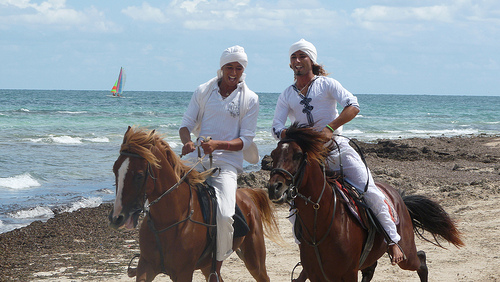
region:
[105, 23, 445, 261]
two riders talking to each other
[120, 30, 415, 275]
two people in white outfits and turbans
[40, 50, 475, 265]
brown horses running along beach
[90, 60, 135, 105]
colorful sailboat on the ocean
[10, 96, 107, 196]
small waves with white caps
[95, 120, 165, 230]
white stripe down the front of horse's head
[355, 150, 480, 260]
tail flying to one side of moving horse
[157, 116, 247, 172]
both hands holding the reins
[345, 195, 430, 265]
bare foot in a stirrup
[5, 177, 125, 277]
seaweed along the edge of the shore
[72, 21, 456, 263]
two men riding horses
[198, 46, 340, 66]
the turbans on the men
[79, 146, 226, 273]
the face of the white and brown horse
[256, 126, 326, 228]
the face of the darker horse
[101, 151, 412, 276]
two horses running on the beach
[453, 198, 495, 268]
the sand that the horses are running on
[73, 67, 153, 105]
a sail boat in the back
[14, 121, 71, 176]
waves on the side of the ocean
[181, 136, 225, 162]
the man holding onto ropes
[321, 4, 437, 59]
clouds in the sky back ground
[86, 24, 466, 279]
two men on horses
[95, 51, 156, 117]
a sail boat on the water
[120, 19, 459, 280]
two men wearing white turbans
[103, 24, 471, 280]
men riding horses on the beach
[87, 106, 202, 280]
a brown and white horse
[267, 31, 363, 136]
man with facial hair on his chin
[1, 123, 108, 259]
waves crash onto the beach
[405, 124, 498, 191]
seaweed washed onto the beach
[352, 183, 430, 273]
a bare foot in a stirrup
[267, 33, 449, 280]
man in white clothing riding a horse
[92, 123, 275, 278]
a galloping brown and white horse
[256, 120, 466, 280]
a galloping brown and white horse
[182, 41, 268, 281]
a man riding a horse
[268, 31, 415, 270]
a barefoot man riding a horse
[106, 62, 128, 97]
a colorful sailboat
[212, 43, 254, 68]
a head turban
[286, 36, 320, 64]
a head turban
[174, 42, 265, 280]
a man wearing a white shirt and pants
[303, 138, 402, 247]
a pair of white pants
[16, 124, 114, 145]
breaking waves in the water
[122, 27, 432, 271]
two people on brown horses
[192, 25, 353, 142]
two people wearing white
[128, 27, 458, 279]
two people wearing white head coverings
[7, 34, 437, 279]
two people on horses on beach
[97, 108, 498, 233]
two brown horses with black saddles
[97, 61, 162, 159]
one boat in ocean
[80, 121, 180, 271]
one brown and white horse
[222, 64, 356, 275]
one totally brown horse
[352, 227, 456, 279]
man has no shoes on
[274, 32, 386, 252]
man wearing white shirt with blue embellishment